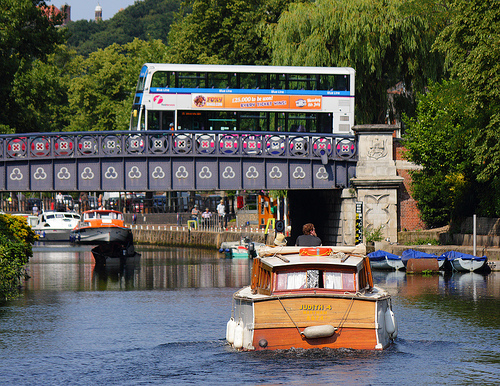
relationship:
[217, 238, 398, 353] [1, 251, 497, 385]
boat in water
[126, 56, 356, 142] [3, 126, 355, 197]
bus driving over bridge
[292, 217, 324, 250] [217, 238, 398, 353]
man on boat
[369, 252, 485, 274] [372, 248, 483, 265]
boats with blue tarps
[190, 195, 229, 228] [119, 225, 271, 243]
people on side walk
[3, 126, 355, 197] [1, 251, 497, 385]
bridge over river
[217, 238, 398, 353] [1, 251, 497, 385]
boat in river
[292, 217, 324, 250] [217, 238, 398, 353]
man stand on boat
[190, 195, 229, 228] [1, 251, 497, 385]
people walking near river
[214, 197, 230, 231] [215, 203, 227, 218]
person wearing white shirt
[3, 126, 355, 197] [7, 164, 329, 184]
bridge has decorations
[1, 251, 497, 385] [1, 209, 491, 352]
river full of boats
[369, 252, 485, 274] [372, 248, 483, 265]
boats covered with tarps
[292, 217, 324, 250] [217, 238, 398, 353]
person on a boat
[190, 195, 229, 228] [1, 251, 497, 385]
people looking over river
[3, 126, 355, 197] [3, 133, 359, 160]
raling with circles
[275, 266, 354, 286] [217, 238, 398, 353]
windows of a boat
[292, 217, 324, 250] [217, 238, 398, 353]
man riding a boat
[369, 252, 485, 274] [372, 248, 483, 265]
boats with blue covers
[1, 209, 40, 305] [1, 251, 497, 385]
bush on side river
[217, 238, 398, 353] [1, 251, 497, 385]
boat on water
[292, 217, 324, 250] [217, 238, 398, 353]
man sitting on boat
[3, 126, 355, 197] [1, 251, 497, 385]
bridge over water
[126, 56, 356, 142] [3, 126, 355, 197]
bus crossing bridge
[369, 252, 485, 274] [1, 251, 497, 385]
boats are on water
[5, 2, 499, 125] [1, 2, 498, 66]
trees growing in background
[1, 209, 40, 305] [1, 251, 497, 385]
bushes near water